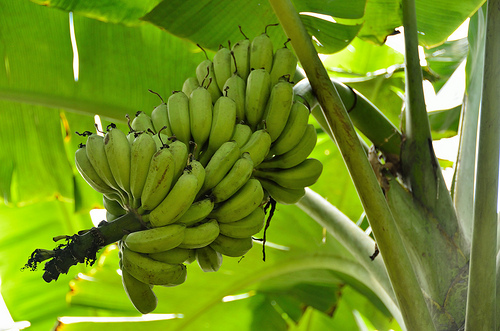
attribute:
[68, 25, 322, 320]
bananas — growing, ripening, green, cluster, attatched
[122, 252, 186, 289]
banana — green, unripe, crescent, sickle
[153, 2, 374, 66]
leaf — green, banana, large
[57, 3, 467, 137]
leaves — green, large, turning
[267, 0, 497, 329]
tree — banana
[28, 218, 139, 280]
stem — thick, green